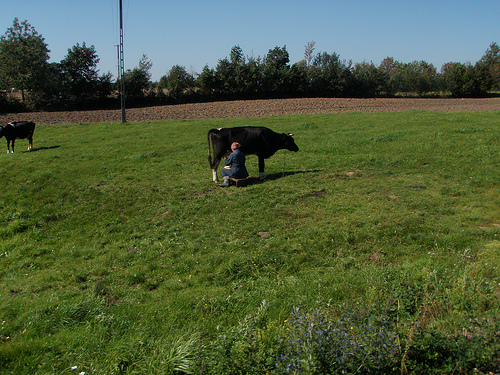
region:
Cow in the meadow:
[201, 116, 306, 189]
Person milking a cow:
[213, 132, 253, 188]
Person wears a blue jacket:
[215, 132, 255, 192]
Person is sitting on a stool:
[212, 135, 257, 191]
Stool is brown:
[225, 171, 245, 183]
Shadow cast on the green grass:
[250, 155, 330, 192]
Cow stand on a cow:
[5, 112, 46, 154]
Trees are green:
[0, 11, 495, 97]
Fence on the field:
[0, 90, 496, 116]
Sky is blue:
[0, 0, 494, 69]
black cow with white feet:
[201, 119, 303, 185]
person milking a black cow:
[216, 142, 248, 192]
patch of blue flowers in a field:
[268, 296, 405, 373]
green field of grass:
[0, 118, 499, 373]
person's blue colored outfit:
[222, 150, 245, 177]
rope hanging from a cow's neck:
[281, 147, 288, 178]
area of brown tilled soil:
[1, 93, 497, 122]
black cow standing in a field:
[2, 115, 42, 155]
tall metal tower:
[119, 0, 128, 125]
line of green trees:
[1, 17, 497, 97]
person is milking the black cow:
[209, 141, 253, 191]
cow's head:
[280, 128, 307, 151]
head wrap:
[225, 140, 241, 150]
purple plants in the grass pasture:
[236, 296, 398, 368]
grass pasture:
[346, 129, 472, 252]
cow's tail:
[193, 121, 221, 168]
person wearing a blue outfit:
[215, 140, 255, 183]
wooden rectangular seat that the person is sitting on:
[225, 171, 250, 186]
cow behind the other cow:
[0, 112, 47, 154]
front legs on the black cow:
[256, 150, 275, 186]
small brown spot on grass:
[335, 166, 382, 186]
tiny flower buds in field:
[285, 302, 379, 337]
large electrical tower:
[106, 17, 150, 127]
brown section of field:
[146, 80, 405, 122]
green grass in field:
[72, 181, 406, 287]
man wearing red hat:
[226, 136, 248, 151]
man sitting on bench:
[215, 169, 272, 186]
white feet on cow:
[193, 156, 230, 198]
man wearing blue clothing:
[213, 146, 255, 178]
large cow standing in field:
[8, 114, 68, 171]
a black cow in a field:
[199, 122, 300, 184]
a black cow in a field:
[1, 119, 44, 154]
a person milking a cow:
[216, 142, 251, 197]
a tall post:
[109, 0, 143, 132]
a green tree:
[1, 17, 56, 113]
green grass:
[0, 105, 494, 370]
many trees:
[1, 17, 498, 114]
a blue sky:
[0, 0, 499, 90]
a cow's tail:
[204, 127, 216, 174]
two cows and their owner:
[0, 110, 298, 195]